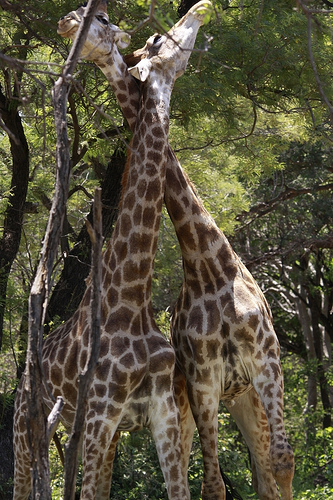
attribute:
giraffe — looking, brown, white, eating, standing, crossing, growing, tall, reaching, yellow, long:
[45, 1, 217, 499]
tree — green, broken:
[171, 3, 332, 162]